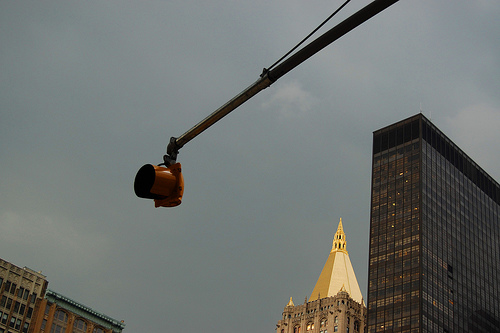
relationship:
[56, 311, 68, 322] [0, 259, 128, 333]
window of a building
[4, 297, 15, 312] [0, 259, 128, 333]
window of a building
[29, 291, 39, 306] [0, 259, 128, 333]
window of a building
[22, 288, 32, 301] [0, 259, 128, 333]
window of a building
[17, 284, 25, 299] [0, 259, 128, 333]
window of a building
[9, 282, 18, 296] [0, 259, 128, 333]
window of a building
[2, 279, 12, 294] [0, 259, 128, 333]
window of a building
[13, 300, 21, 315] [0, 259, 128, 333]
window of a building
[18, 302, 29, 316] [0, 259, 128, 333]
window of a building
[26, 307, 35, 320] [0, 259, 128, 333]
window of a building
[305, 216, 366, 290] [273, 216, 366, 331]
golden pyramid on top of a sky scraper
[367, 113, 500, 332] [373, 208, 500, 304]
building with many window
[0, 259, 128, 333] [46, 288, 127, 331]
apartment building has a green top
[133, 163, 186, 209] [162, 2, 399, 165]
traffic signal has a metal arm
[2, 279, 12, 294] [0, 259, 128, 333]
window on side of building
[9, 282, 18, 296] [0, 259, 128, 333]
window on side of building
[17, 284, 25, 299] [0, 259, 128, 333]
window on side of building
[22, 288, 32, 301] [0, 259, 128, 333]
window on side of building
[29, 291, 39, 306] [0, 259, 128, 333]
window on side of building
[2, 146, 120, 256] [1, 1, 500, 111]
gray clouds in sky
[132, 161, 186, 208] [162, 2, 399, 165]
light on end of pole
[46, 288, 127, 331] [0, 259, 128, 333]
roof of building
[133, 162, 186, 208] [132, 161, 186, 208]
cone around light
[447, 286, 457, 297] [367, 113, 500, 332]
small speck on side of building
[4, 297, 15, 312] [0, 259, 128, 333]
window on side of building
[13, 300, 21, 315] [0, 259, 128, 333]
window on side of building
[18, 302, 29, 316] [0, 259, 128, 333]
window on side of building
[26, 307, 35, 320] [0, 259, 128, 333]
window on side of building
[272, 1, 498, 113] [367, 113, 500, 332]
clouds above building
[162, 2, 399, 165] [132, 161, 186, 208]
pole holding street light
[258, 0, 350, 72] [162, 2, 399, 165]
cord on top of pole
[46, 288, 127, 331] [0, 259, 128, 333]
top of building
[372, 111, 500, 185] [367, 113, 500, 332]
top of building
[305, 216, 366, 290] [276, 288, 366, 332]
top of building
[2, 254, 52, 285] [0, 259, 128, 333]
roof of a building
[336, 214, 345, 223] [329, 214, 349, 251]
point on top of roof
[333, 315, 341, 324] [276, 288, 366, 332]
window of a building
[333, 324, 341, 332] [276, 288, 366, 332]
window of a building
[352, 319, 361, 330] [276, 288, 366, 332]
window of a building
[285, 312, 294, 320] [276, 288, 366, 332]
window of a building